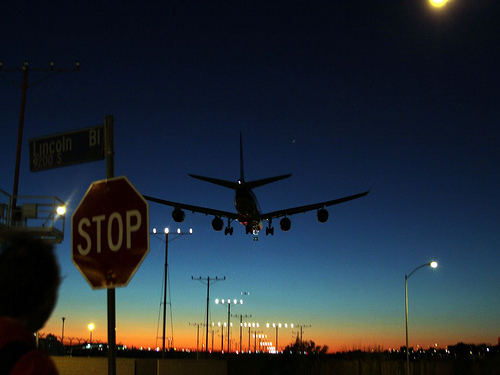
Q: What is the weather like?
A: It is clear.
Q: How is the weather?
A: It is clear.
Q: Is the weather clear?
A: Yes, it is clear.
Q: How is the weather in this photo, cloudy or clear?
A: It is clear.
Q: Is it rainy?
A: No, it is clear.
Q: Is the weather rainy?
A: No, it is clear.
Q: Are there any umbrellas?
A: No, there are no umbrellas.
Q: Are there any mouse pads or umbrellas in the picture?
A: No, there are no umbrellas or mouse pads.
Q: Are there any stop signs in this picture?
A: Yes, there is a stop sign.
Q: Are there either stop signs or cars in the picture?
A: Yes, there is a stop sign.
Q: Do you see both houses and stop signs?
A: No, there is a stop sign but no houses.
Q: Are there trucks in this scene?
A: No, there are no trucks.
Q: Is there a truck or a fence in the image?
A: No, there are no trucks or fences.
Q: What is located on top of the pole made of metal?
A: The stop sign is on top of the pole.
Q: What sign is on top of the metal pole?
A: The sign is a stop sign.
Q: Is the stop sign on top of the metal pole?
A: Yes, the stop sign is on top of the pole.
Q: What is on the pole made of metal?
A: The stop sign is on the pole.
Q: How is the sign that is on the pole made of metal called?
A: The sign is a stop sign.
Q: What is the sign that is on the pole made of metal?
A: The sign is a stop sign.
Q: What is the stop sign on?
A: The stop sign is on the pole.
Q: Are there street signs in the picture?
A: Yes, there is a street sign.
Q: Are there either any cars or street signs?
A: Yes, there is a street sign.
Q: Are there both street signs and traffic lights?
A: No, there is a street sign but no traffic lights.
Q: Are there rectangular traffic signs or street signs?
A: Yes, there is a rectangular street sign.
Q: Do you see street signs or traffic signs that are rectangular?
A: Yes, the street sign is rectangular.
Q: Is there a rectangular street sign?
A: Yes, there is a rectangular street sign.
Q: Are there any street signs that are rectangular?
A: Yes, there is a street sign that is rectangular.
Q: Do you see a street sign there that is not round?
A: Yes, there is a rectangular street sign.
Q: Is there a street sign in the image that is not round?
A: Yes, there is a rectangular street sign.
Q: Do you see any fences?
A: No, there are no fences.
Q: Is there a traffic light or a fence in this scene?
A: No, there are no fences or traffic lights.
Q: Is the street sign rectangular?
A: Yes, the street sign is rectangular.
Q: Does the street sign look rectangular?
A: Yes, the street sign is rectangular.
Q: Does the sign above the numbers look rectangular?
A: Yes, the street sign is rectangular.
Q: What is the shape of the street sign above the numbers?
A: The street sign is rectangular.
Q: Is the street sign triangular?
A: No, the street sign is rectangular.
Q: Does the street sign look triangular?
A: No, the street sign is rectangular.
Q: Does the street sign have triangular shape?
A: No, the street sign is rectangular.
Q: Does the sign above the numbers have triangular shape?
A: No, the street sign is rectangular.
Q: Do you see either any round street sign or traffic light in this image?
A: No, there is a street sign but it is rectangular.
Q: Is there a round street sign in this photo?
A: No, there is a street sign but it is rectangular.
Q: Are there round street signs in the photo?
A: No, there is a street sign but it is rectangular.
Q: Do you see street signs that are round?
A: No, there is a street sign but it is rectangular.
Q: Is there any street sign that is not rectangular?
A: No, there is a street sign but it is rectangular.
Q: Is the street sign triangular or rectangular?
A: The street sign is rectangular.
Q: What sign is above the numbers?
A: The sign is a street sign.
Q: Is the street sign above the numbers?
A: Yes, the street sign is above the numbers.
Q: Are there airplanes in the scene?
A: Yes, there is an airplane.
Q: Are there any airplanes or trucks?
A: Yes, there is an airplane.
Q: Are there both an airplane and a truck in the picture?
A: No, there is an airplane but no trucks.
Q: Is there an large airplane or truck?
A: Yes, there is a large airplane.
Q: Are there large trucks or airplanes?
A: Yes, there is a large airplane.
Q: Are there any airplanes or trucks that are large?
A: Yes, the airplane is large.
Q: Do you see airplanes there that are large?
A: Yes, there is a large airplane.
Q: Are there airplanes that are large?
A: Yes, there is an airplane that is large.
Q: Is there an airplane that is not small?
A: Yes, there is a large airplane.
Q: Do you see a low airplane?
A: Yes, there is a low airplane.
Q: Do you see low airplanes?
A: Yes, there is a low airplane.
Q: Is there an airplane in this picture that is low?
A: Yes, there is an airplane that is low.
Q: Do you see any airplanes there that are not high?
A: Yes, there is a low airplane.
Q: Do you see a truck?
A: No, there are no trucks.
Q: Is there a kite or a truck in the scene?
A: No, there are no trucks or kites.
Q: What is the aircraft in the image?
A: The aircraft is an airplane.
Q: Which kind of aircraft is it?
A: The aircraft is an airplane.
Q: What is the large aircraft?
A: The aircraft is an airplane.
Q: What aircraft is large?
A: The aircraft is an airplane.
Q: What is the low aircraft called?
A: The aircraft is an airplane.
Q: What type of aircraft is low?
A: The aircraft is an airplane.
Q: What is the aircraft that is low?
A: The aircraft is an airplane.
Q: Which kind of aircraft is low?
A: The aircraft is an airplane.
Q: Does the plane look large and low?
A: Yes, the plane is large and low.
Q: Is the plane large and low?
A: Yes, the plane is large and low.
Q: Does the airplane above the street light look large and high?
A: No, the airplane is large but low.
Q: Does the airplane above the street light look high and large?
A: No, the airplane is large but low.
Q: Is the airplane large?
A: Yes, the airplane is large.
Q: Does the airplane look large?
A: Yes, the airplane is large.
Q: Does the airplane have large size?
A: Yes, the airplane is large.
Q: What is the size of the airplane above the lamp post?
A: The plane is large.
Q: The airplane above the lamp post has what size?
A: The plane is large.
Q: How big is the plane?
A: The plane is large.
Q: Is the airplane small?
A: No, the airplane is large.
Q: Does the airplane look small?
A: No, the airplane is large.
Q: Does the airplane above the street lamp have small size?
A: No, the plane is large.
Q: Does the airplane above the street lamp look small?
A: No, the plane is large.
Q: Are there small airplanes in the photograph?
A: No, there is an airplane but it is large.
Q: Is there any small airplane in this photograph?
A: No, there is an airplane but it is large.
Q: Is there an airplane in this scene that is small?
A: No, there is an airplane but it is large.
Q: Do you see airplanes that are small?
A: No, there is an airplane but it is large.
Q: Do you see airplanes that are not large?
A: No, there is an airplane but it is large.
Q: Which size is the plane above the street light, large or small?
A: The airplane is large.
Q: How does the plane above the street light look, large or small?
A: The airplane is large.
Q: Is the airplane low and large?
A: Yes, the airplane is low and large.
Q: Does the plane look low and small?
A: No, the plane is low but large.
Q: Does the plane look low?
A: Yes, the plane is low.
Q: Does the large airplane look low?
A: Yes, the plane is low.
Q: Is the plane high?
A: No, the plane is low.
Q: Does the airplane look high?
A: No, the airplane is low.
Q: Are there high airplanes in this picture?
A: No, there is an airplane but it is low.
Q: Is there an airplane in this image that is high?
A: No, there is an airplane but it is low.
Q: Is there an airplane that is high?
A: No, there is an airplane but it is low.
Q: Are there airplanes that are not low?
A: No, there is an airplane but it is low.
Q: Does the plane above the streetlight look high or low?
A: The plane is low.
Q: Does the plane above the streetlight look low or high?
A: The plane is low.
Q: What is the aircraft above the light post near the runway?
A: The aircraft is an airplane.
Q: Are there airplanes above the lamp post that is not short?
A: Yes, there is an airplane above the streetlight.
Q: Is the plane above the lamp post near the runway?
A: Yes, the plane is above the light post.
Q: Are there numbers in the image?
A: Yes, there are numbers.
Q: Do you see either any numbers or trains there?
A: Yes, there are numbers.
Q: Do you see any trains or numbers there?
A: Yes, there are numbers.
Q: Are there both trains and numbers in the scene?
A: No, there are numbers but no trains.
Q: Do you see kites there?
A: No, there are no kites.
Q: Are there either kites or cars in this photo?
A: No, there are no kites or cars.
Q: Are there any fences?
A: No, there are no fences.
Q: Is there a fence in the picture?
A: No, there are no fences.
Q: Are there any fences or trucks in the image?
A: No, there are no fences or trucks.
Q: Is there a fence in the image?
A: No, there are no fences.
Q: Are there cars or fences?
A: No, there are no fences or cars.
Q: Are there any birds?
A: No, there are no birds.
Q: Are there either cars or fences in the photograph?
A: No, there are no fences or cars.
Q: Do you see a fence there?
A: No, there are no fences.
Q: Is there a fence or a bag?
A: No, there are no fences or bags.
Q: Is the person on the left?
A: Yes, the person is on the left of the image.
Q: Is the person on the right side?
A: No, the person is on the left of the image.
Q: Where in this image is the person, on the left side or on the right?
A: The person is on the left of the image.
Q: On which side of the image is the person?
A: The person is on the left of the image.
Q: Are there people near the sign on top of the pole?
A: Yes, there is a person near the stop sign.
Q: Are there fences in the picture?
A: No, there are no fences.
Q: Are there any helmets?
A: No, there are no helmets.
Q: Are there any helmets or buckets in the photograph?
A: No, there are no helmets or buckets.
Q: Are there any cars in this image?
A: No, there are no cars.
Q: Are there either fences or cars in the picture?
A: No, there are no cars or fences.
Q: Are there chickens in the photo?
A: No, there are no chickens.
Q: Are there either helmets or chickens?
A: No, there are no chickens or helmets.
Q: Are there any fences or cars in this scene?
A: No, there are no fences or cars.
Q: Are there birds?
A: No, there are no birds.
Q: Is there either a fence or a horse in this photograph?
A: No, there are no fences or horses.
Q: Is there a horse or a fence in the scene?
A: No, there are no fences or horses.